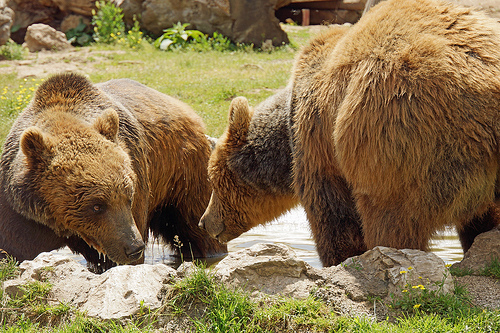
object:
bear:
[0, 71, 225, 277]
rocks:
[0, 240, 455, 318]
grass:
[0, 262, 499, 332]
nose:
[127, 240, 148, 258]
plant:
[0, 0, 301, 138]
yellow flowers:
[107, 31, 126, 42]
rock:
[26, 18, 72, 52]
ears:
[95, 105, 125, 138]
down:
[90, 194, 113, 266]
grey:
[121, 285, 144, 301]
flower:
[88, 0, 148, 48]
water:
[95, 210, 499, 273]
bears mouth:
[108, 236, 151, 268]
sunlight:
[0, 32, 293, 139]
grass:
[0, 0, 316, 135]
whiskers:
[87, 234, 136, 266]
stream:
[154, 194, 471, 270]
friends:
[199, 0, 500, 266]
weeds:
[90, 4, 153, 46]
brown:
[423, 71, 443, 94]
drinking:
[90, 248, 179, 268]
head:
[15, 114, 154, 260]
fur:
[0, 72, 224, 265]